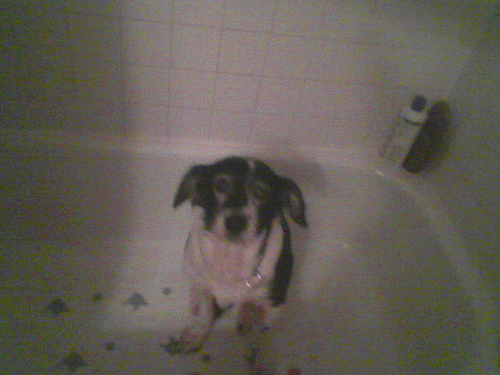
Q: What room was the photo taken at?
A: It was taken at the bathroom.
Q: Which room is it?
A: It is a bathroom.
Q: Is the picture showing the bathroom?
A: Yes, it is showing the bathroom.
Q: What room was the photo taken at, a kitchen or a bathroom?
A: It was taken at a bathroom.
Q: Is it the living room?
A: No, it is the bathroom.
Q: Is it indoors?
A: Yes, it is indoors.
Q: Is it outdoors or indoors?
A: It is indoors.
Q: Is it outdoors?
A: No, it is indoors.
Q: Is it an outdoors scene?
A: No, it is indoors.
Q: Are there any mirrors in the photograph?
A: No, there are no mirrors.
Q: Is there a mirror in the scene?
A: No, there are no mirrors.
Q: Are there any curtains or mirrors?
A: No, there are no mirrors or curtains.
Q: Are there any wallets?
A: No, there are no wallets.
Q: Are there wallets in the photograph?
A: No, there are no wallets.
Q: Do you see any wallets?
A: No, there are no wallets.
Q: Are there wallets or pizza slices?
A: No, there are no wallets or pizza slices.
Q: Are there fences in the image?
A: No, there are no fences.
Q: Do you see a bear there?
A: No, there are no bears.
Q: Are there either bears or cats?
A: No, there are no bears or cats.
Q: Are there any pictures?
A: No, there are no pictures.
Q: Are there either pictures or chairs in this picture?
A: No, there are no pictures or chairs.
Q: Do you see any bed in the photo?
A: No, there are no beds.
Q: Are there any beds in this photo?
A: No, there are no beds.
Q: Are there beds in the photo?
A: No, there are no beds.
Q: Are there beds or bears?
A: No, there are no beds or bears.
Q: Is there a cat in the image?
A: No, there are no cats.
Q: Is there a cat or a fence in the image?
A: No, there are no cats or fences.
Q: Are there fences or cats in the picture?
A: No, there are no cats or fences.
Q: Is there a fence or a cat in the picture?
A: No, there are no cats or fences.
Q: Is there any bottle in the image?
A: Yes, there is a bottle.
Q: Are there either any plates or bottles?
A: Yes, there is a bottle.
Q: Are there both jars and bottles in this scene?
A: No, there is a bottle but no jars.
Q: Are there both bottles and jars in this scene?
A: No, there is a bottle but no jars.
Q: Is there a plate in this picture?
A: No, there are no plates.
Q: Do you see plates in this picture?
A: No, there are no plates.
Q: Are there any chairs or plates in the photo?
A: No, there are no plates or chairs.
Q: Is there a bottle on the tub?
A: Yes, there is a bottle on the tub.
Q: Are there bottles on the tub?
A: Yes, there is a bottle on the tub.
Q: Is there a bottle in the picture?
A: Yes, there is a bottle.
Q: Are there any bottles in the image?
A: Yes, there is a bottle.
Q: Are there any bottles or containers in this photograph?
A: Yes, there is a bottle.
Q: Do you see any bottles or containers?
A: Yes, there is a bottle.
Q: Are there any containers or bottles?
A: Yes, there is a bottle.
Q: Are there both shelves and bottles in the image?
A: No, there is a bottle but no shelves.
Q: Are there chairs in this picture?
A: No, there are no chairs.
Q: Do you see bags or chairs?
A: No, there are no chairs or bags.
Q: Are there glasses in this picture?
A: No, there are no glasses.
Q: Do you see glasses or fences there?
A: No, there are no glasses or fences.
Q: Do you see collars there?
A: Yes, there is a collar.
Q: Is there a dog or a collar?
A: Yes, there is a collar.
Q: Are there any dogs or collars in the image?
A: Yes, there is a collar.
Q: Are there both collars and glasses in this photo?
A: No, there is a collar but no glasses.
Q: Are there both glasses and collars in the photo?
A: No, there is a collar but no glasses.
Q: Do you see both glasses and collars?
A: No, there is a collar but no glasses.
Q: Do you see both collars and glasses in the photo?
A: No, there is a collar but no glasses.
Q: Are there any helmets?
A: No, there are no helmets.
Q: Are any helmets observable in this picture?
A: No, there are no helmets.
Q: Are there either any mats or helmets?
A: No, there are no helmets or mats.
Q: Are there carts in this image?
A: No, there are no carts.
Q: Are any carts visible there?
A: No, there are no carts.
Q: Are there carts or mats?
A: No, there are no carts or mats.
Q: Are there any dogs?
A: Yes, there is a dog.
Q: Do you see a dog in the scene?
A: Yes, there is a dog.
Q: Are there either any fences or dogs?
A: Yes, there is a dog.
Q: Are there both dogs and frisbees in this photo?
A: No, there is a dog but no frisbees.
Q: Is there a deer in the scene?
A: No, there is no deer.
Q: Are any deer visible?
A: No, there are no deer.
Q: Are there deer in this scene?
A: No, there are no deer.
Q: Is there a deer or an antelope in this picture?
A: No, there are no deer or antelopes.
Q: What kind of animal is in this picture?
A: The animal is a dog.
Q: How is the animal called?
A: The animal is a dog.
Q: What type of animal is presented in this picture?
A: The animal is a dog.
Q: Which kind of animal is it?
A: The animal is a dog.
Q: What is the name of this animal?
A: That is a dog.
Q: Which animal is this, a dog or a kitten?
A: That is a dog.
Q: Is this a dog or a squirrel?
A: This is a dog.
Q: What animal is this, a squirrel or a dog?
A: This is a dog.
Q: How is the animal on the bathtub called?
A: The animal is a dog.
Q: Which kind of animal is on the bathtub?
A: The animal is a dog.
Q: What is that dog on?
A: The dog is on the bathtub.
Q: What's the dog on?
A: The dog is on the bathtub.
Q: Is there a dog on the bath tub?
A: Yes, there is a dog on the bath tub.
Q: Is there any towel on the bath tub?
A: No, there is a dog on the bath tub.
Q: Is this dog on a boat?
A: No, the dog is on the bathtub.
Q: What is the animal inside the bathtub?
A: The animal is a dog.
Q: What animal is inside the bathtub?
A: The animal is a dog.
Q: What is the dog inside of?
A: The dog is inside the bathtub.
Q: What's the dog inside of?
A: The dog is inside the bathtub.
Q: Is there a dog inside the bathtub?
A: Yes, there is a dog inside the bathtub.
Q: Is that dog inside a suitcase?
A: No, the dog is inside a bathtub.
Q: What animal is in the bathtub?
A: The dog is in the bathtub.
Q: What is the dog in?
A: The dog is in the bathtub.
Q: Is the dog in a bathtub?
A: Yes, the dog is in a bathtub.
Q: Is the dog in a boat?
A: No, the dog is in a bathtub.